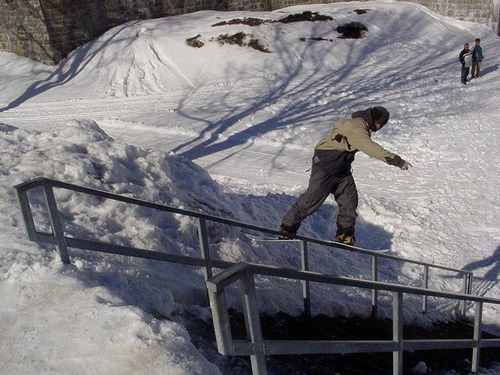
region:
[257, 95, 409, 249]
Man snowboarding on rail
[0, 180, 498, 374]
Two silver rails on stairs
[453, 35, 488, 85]
Two people watching snowboarder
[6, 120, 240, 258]
Pile of dirty snow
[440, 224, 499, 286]
Shadow of snowboarder on snow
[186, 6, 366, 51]
Patches of dirt on snowy hill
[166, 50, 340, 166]
Shadow of tree on snow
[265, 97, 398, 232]
Man wearing gray pants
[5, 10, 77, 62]
Brick wall in background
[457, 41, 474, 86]
Man wearing black and white jacket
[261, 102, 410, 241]
a boarder on a railing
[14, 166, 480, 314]
railing going down a stairway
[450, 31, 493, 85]
two people watching a boarder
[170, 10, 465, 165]
shadow of a tree in the snow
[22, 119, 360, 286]
a snow pile alongside a stairway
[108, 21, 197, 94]
tracks going down a hill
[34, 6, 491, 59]
a snowy hill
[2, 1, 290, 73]
a brick building behind a hill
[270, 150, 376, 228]
gray pants on a boarder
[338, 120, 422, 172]
an outstretched arm of a boarder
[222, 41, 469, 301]
a person skiing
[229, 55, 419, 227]
a person with a jacket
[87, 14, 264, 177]
snow on the ground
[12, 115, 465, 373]
stairs going down on the snow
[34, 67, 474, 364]
stairs with metal poles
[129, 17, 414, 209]
snow in during the day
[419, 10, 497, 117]
two people standing in the snow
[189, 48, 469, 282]
a person skiing during the day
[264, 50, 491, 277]
a person leaning forward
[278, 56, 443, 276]
leaning forward on skies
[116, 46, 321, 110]
The snow is on the ground.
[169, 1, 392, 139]
A shadow of a tree on the snow.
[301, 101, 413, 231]
A person is skiing.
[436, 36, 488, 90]
Two people standing in the background.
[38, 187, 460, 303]
Railings on the side of the person.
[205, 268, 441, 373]
Railings are made out of iron.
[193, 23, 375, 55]
Dirt is on the snow.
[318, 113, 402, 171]
The person is wearing a brown jacket.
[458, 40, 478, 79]
The person have his hand in his pockets.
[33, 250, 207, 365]
The stairs is full with snow.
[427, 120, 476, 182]
part of a snow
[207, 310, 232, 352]
part of a metal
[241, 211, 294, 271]
part of a balcony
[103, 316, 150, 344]
part of a snow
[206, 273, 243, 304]
edge of a metal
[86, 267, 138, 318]
part of a snow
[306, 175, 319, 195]
part of a trouser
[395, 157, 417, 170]
part of a hand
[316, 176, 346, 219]
part of a trouser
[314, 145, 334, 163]
part of a sweater